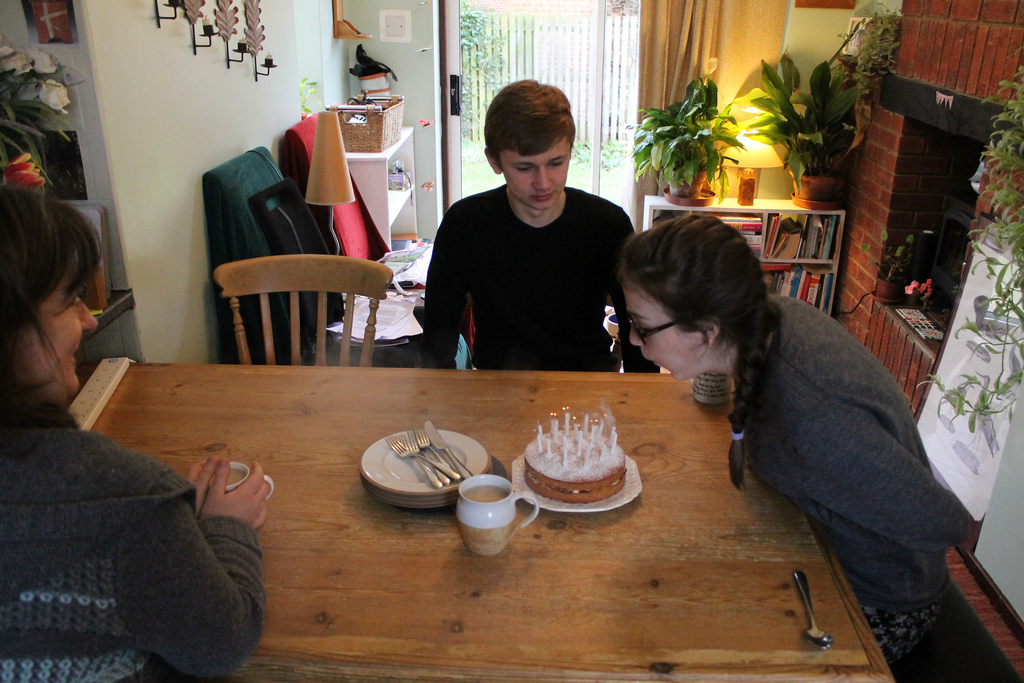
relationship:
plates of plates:
[359, 427, 494, 507] [331, 377, 532, 525]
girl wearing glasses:
[601, 201, 1016, 675] [595, 286, 699, 364]